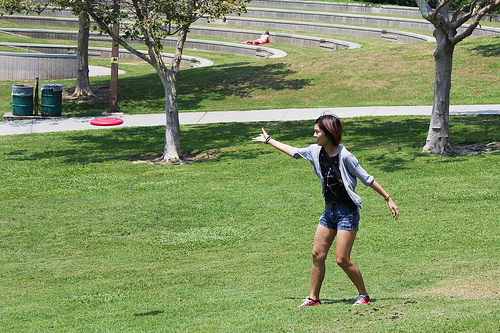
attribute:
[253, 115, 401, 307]
woman — standing, light-skinned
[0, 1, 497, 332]
park — grassy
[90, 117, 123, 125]
frisbee — airborne, red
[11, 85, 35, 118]
garbage-can — green, barrel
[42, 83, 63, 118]
garbage-can — green, barrel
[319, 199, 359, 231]
shorts — jeans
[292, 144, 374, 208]
cardigan — gray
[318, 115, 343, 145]
hair — short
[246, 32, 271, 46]
person — sunbathing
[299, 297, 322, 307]
shoe — red, converse, low-top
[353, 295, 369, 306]
shoe — red, converse, low-top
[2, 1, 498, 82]
amphitheater — round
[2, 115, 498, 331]
grass — green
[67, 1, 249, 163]
tree — green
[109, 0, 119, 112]
pole — brown